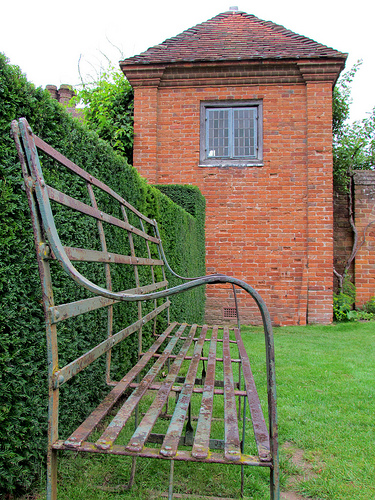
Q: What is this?
A: Bench.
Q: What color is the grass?
A: Green.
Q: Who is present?
A: Nobody.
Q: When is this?
A: Daytime.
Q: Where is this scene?
A: In a park.